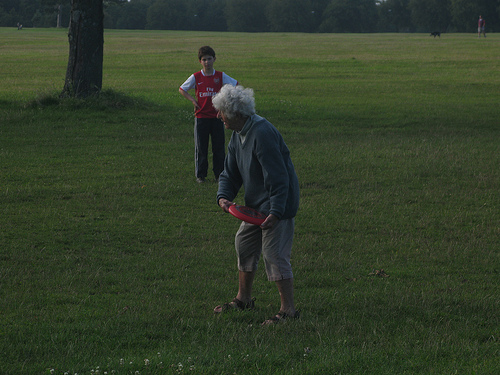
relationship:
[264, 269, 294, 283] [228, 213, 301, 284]
edge of short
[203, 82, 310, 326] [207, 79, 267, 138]
man seen head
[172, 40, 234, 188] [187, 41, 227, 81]
boy seen head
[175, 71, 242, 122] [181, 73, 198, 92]
shirt has sleeve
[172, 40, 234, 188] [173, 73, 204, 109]
boy seen arm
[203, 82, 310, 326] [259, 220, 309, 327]
man seen a leg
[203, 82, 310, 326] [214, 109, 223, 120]
man seen a nose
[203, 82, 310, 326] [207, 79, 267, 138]
man has white hair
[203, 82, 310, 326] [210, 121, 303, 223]
man has gray sweater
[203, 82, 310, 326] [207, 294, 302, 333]
man wearing sandals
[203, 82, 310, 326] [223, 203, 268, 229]
man holding frisbee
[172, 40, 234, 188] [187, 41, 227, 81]
boy hair brown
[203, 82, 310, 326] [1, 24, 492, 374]
man playing on grass area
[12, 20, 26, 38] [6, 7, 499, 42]
dog in background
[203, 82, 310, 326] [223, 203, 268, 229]
woman holding frisbee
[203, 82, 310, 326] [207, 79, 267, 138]
woman has grey hair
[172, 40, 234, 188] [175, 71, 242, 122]
boy wearing shirt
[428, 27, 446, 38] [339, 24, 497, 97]
dog walking in field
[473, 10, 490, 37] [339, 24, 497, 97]
person walking in field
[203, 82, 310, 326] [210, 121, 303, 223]
woman wearing grey shirt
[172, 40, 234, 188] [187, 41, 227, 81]
boy with brown hair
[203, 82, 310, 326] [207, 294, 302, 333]
woman wearing sandles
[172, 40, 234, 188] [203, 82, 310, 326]
boy with h grandmother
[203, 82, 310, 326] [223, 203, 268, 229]
woman has red frisbee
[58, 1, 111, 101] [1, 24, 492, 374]
tree in park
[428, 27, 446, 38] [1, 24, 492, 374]
dog running in park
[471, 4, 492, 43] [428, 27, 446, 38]
owner running after dog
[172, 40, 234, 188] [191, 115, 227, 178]
boy wearing jogging pants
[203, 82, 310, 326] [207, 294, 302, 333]
woman wearing sandals